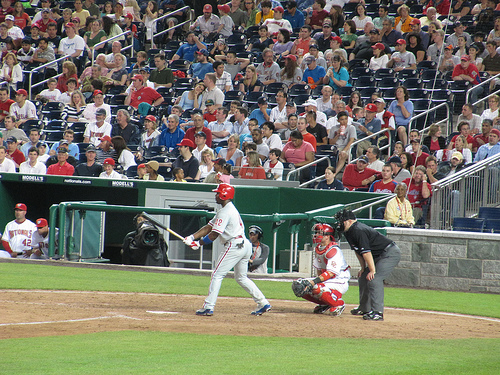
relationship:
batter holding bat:
[182, 174, 276, 324] [132, 205, 208, 255]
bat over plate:
[132, 205, 208, 255] [136, 302, 185, 324]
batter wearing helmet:
[182, 174, 276, 324] [212, 179, 243, 201]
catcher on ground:
[284, 215, 368, 325] [0, 260, 499, 374]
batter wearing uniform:
[182, 174, 276, 324] [200, 200, 268, 310]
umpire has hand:
[331, 205, 411, 337] [364, 268, 380, 280]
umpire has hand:
[331, 205, 411, 337] [356, 268, 365, 278]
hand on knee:
[364, 268, 380, 280] [363, 274, 375, 286]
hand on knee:
[356, 268, 365, 278] [354, 275, 365, 282]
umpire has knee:
[331, 205, 411, 337] [363, 274, 375, 286]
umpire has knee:
[331, 205, 411, 337] [354, 275, 365, 282]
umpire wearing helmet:
[331, 205, 411, 337] [330, 205, 358, 235]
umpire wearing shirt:
[331, 205, 411, 337] [343, 218, 402, 258]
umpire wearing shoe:
[331, 205, 411, 337] [360, 309, 389, 325]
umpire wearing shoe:
[331, 205, 411, 337] [346, 302, 373, 320]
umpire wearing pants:
[331, 205, 411, 337] [348, 239, 403, 314]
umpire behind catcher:
[331, 205, 411, 337] [284, 215, 368, 325]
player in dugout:
[0, 200, 41, 267] [1, 176, 393, 284]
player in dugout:
[29, 215, 68, 270] [1, 176, 393, 284]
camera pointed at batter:
[134, 222, 162, 252] [182, 183, 272, 316]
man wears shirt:
[380, 179, 415, 226] [384, 196, 415, 223]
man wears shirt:
[251, 95, 276, 127] [247, 108, 272, 120]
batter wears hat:
[182, 183, 272, 316] [218, 174, 253, 206]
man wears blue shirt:
[334, 203, 403, 322] [302, 66, 329, 87]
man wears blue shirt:
[390, 34, 419, 74] [157, 122, 188, 151]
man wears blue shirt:
[367, 159, 401, 195] [173, 37, 211, 63]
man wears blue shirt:
[45, 142, 78, 177] [280, 5, 311, 33]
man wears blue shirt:
[2, 198, 47, 259] [324, 62, 354, 90]